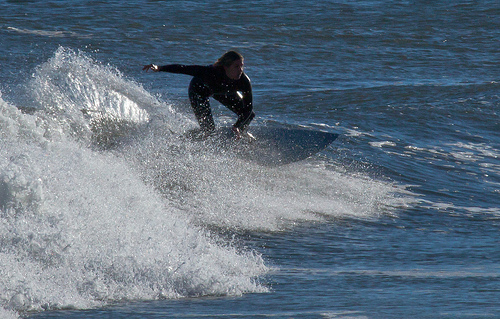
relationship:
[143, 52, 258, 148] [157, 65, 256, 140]
person wearing suit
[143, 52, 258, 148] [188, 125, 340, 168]
person on surboard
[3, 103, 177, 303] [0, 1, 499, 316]
wave in water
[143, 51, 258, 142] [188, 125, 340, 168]
person on surboard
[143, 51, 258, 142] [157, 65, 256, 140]
person wears suit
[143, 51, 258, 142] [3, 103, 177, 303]
person ride wave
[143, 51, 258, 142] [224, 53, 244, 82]
person has face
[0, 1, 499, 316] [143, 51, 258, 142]
water behind person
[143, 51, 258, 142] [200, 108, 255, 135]
person has knees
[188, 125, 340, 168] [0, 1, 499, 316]
surboard in water